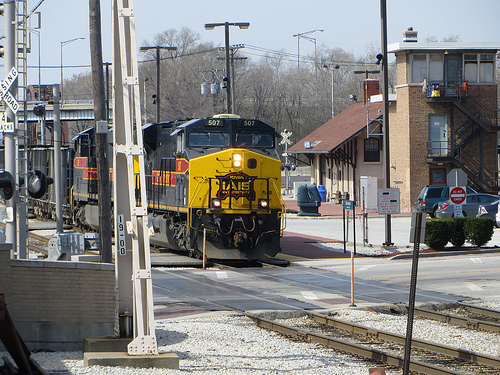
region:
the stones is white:
[197, 331, 277, 371]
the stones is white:
[215, 322, 257, 360]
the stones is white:
[187, 314, 238, 362]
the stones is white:
[230, 328, 252, 366]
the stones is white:
[237, 335, 274, 362]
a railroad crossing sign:
[0, 63, 35, 128]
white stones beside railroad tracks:
[162, 320, 347, 371]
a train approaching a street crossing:
[8, 107, 426, 319]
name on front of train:
[205, 163, 265, 208]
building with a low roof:
[276, 70, 391, 220]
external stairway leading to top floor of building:
[390, 45, 496, 215]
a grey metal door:
[415, 105, 453, 161]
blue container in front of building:
[308, 155, 358, 200]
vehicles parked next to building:
[397, 140, 497, 240]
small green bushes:
[410, 211, 498, 253]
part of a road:
[221, 283, 248, 307]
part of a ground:
[191, 315, 228, 352]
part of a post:
[401, 275, 423, 331]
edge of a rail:
[296, 317, 343, 366]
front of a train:
[222, 192, 292, 268]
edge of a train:
[174, 193, 192, 235]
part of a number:
[113, 222, 145, 302]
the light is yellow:
[220, 142, 288, 189]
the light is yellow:
[209, 102, 290, 274]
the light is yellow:
[228, 140, 271, 207]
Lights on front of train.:
[209, 138, 310, 280]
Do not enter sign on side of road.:
[436, 170, 488, 282]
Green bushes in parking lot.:
[413, 208, 491, 231]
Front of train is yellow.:
[195, 110, 305, 303]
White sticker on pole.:
[103, 204, 128, 289]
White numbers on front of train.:
[200, 112, 285, 133]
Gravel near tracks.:
[208, 320, 288, 373]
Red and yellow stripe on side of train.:
[79, 153, 213, 210]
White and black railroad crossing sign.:
[2, 78, 26, 120]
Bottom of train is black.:
[203, 225, 279, 280]